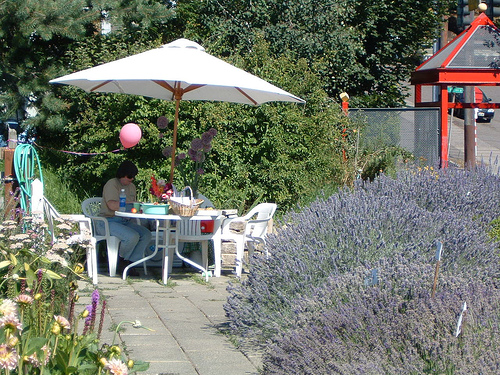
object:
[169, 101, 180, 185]
pole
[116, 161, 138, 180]
hair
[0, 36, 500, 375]
patio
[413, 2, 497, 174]
structure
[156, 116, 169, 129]
balloons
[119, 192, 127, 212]
water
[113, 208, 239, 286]
table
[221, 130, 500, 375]
bush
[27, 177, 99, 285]
chair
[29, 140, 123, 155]
string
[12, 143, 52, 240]
garden hose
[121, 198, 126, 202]
label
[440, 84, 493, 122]
car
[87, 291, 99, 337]
flower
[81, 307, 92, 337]
flower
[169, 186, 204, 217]
basket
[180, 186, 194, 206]
handle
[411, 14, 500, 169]
booth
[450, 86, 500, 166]
glass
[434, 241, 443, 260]
paper sign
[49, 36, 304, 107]
umbrella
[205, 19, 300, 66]
sun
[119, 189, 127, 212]
bottle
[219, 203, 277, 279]
chair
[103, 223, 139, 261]
legs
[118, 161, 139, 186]
head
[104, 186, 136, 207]
arm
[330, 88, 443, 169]
stop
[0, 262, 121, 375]
shrubs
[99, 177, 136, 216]
shirt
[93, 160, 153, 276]
woman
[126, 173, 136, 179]
sunglasses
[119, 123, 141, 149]
balloon